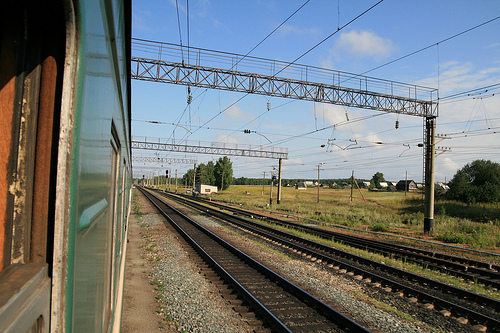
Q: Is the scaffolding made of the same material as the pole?
A: Yes, both the scaffolding and the pole are made of metal.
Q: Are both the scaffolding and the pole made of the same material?
A: Yes, both the scaffolding and the pole are made of metal.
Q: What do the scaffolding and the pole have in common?
A: The material, both the scaffolding and the pole are metallic.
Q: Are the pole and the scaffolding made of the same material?
A: Yes, both the pole and the scaffolding are made of metal.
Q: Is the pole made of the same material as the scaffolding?
A: Yes, both the pole and the scaffolding are made of metal.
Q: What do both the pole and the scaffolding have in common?
A: The material, both the pole and the scaffolding are metallic.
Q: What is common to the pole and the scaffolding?
A: The material, both the pole and the scaffolding are metallic.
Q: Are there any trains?
A: Yes, there is a train.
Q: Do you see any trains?
A: Yes, there is a train.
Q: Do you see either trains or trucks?
A: Yes, there is a train.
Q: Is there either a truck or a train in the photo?
A: Yes, there is a train.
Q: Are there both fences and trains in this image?
A: No, there is a train but no fences.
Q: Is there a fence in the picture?
A: No, there are no fences.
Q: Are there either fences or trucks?
A: No, there are no fences or trucks.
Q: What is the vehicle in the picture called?
A: The vehicle is a train.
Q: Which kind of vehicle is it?
A: The vehicle is a train.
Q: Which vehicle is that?
A: This is a train.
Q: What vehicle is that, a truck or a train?
A: This is a train.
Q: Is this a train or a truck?
A: This is a train.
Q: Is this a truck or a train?
A: This is a train.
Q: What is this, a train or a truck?
A: This is a train.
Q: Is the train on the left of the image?
A: Yes, the train is on the left of the image.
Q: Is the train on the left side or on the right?
A: The train is on the left of the image.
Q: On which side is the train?
A: The train is on the left of the image.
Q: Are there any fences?
A: No, there are no fences.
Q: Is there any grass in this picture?
A: Yes, there is grass.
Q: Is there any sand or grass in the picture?
A: Yes, there is grass.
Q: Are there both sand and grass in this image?
A: No, there is grass but no sand.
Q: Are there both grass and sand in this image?
A: No, there is grass but no sand.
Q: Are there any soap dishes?
A: No, there are no soap dishes.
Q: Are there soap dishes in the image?
A: No, there are no soap dishes.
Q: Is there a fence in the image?
A: No, there are no fences.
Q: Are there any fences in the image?
A: No, there are no fences.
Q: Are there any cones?
A: No, there are no cones.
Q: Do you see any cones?
A: No, there are no cones.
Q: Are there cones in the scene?
A: No, there are no cones.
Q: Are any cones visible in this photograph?
A: No, there are no cones.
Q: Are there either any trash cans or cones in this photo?
A: No, there are no cones or trash cans.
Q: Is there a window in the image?
A: Yes, there is a window.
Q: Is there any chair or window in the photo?
A: Yes, there is a window.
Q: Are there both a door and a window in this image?
A: No, there is a window but no doors.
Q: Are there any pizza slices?
A: No, there are no pizza slices.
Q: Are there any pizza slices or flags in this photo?
A: No, there are no pizza slices or flags.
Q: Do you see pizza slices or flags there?
A: No, there are no pizza slices or flags.